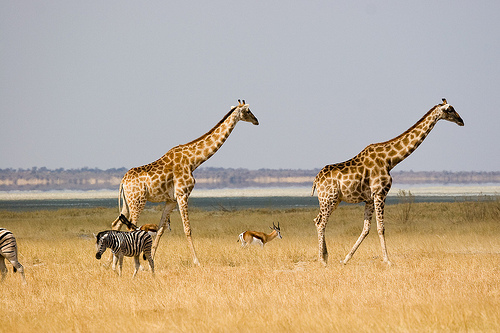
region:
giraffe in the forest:
[308, 95, 479, 274]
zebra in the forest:
[83, 215, 162, 277]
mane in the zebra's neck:
[100, 227, 115, 239]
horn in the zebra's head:
[236, 96, 245, 106]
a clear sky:
[148, 18, 423, 75]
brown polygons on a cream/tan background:
[147, 168, 192, 190]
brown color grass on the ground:
[67, 272, 379, 330]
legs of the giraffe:
[307, 202, 398, 268]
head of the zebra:
[91, 228, 112, 260]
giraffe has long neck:
[315, 101, 450, 236]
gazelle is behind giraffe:
[217, 215, 297, 254]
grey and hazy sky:
[281, 19, 365, 139]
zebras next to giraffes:
[0, 212, 160, 288]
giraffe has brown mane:
[183, 106, 223, 154]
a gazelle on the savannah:
[231, 220, 282, 245]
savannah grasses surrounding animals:
[0, 197, 495, 328]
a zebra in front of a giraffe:
[91, 226, 156, 276]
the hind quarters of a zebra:
[0, 225, 25, 280]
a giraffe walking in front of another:
[302, 95, 462, 262]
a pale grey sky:
[0, 0, 496, 165]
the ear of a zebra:
[100, 230, 105, 240]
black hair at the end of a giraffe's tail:
[115, 210, 136, 227]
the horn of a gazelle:
[275, 218, 280, 226]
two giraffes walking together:
[114, 82, 462, 265]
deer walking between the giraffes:
[233, 219, 280, 259]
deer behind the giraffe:
[137, 210, 173, 245]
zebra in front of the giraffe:
[86, 225, 156, 280]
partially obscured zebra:
[0, 222, 26, 281]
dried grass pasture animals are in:
[7, 204, 498, 331]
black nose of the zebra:
[95, 252, 102, 258]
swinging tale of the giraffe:
[113, 182, 137, 229]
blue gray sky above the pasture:
[2, 1, 496, 168]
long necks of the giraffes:
[185, 116, 443, 173]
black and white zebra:
[90, 225, 166, 276]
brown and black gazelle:
[237, 215, 295, 253]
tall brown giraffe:
[310, 75, 472, 271]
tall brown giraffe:
[116, 88, 263, 276]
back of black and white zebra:
[1, 226, 31, 283]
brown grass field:
[5, 203, 496, 330]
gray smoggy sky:
[3, 2, 489, 179]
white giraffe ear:
[240, 100, 254, 115]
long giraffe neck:
[182, 108, 249, 181]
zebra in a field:
[89, 229, 169, 286]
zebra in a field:
[1, 223, 23, 285]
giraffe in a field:
[103, 103, 255, 250]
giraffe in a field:
[291, 70, 467, 265]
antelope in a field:
[232, 218, 283, 254]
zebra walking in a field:
[87, 225, 162, 270]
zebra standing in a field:
[1, 225, 28, 282]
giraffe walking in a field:
[113, 95, 261, 265]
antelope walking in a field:
[236, 220, 287, 251]